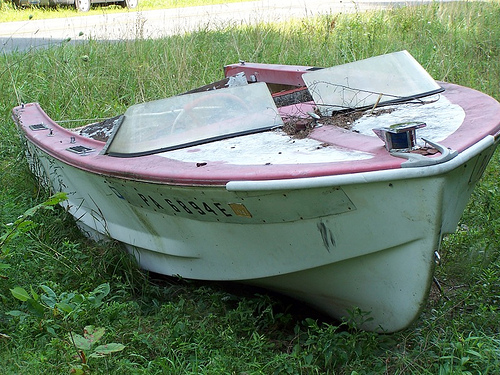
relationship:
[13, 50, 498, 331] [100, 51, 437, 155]
boat on windshield